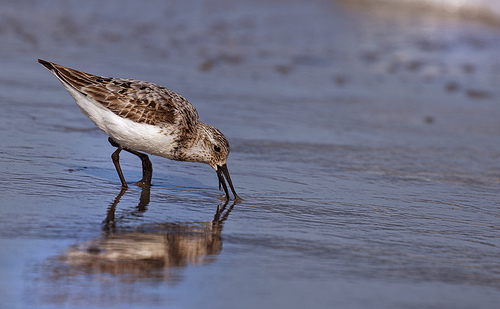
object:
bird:
[40, 58, 242, 209]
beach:
[247, 249, 303, 287]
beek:
[214, 163, 242, 204]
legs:
[108, 150, 130, 192]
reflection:
[65, 230, 226, 280]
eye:
[212, 144, 220, 153]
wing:
[61, 70, 176, 123]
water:
[374, 126, 422, 168]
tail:
[34, 55, 88, 98]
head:
[192, 120, 240, 206]